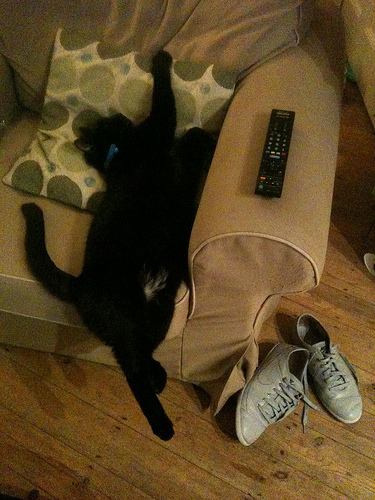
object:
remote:
[252, 104, 299, 203]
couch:
[1, 3, 351, 418]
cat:
[18, 39, 218, 444]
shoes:
[230, 342, 313, 450]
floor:
[0, 76, 375, 500]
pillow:
[2, 25, 240, 214]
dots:
[78, 62, 117, 104]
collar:
[102, 141, 125, 166]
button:
[259, 175, 267, 181]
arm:
[191, 6, 346, 314]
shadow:
[4, 290, 107, 423]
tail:
[19, 200, 80, 307]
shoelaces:
[257, 369, 322, 435]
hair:
[138, 268, 175, 304]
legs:
[105, 338, 176, 444]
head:
[69, 110, 142, 174]